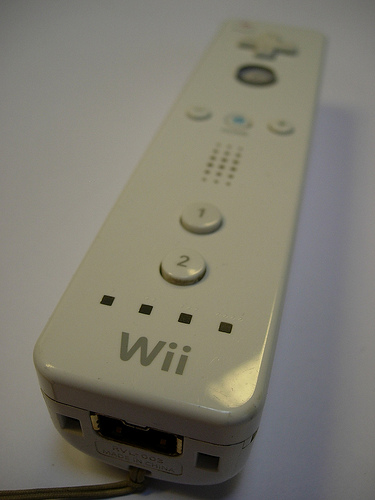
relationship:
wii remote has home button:
[16, 14, 341, 483] [237, 63, 272, 92]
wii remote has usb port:
[16, 14, 341, 483] [93, 409, 183, 458]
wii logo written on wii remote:
[111, 328, 196, 377] [16, 14, 341, 483]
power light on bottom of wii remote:
[100, 292, 116, 308] [16, 14, 341, 483]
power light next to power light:
[178, 311, 195, 326] [216, 318, 236, 336]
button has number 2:
[160, 249, 204, 280] [179, 254, 191, 270]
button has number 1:
[180, 200, 220, 229] [198, 208, 208, 221]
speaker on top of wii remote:
[200, 137, 250, 189] [16, 14, 341, 483]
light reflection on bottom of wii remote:
[206, 344, 266, 414] [16, 14, 341, 483]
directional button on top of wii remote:
[236, 28, 303, 64] [16, 14, 341, 483]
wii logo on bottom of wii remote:
[111, 328, 196, 377] [16, 14, 341, 483]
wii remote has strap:
[16, 14, 341, 483] [2, 454, 148, 499]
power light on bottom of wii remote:
[218, 321, 233, 334] [16, 14, 341, 483]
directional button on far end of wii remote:
[236, 28, 303, 64] [16, 14, 341, 483]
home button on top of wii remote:
[237, 63, 272, 92] [16, 14, 341, 483]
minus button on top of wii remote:
[188, 103, 216, 123] [16, 14, 341, 483]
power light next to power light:
[100, 292, 116, 308] [137, 302, 156, 317]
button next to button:
[160, 249, 204, 280] [180, 200, 220, 229]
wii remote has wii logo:
[16, 14, 341, 483] [111, 328, 196, 377]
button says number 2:
[160, 249, 204, 280] [179, 254, 191, 270]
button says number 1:
[180, 200, 220, 229] [198, 208, 208, 221]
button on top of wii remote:
[181, 201, 221, 234] [16, 14, 341, 483]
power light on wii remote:
[100, 292, 116, 308] [16, 14, 341, 483]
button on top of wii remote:
[160, 249, 204, 280] [16, 14, 341, 483]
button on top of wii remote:
[180, 200, 220, 229] [16, 14, 341, 483]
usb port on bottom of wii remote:
[93, 409, 183, 458] [16, 14, 341, 483]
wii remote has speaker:
[16, 14, 341, 483] [200, 137, 250, 189]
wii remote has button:
[16, 14, 341, 483] [160, 249, 204, 280]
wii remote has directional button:
[16, 14, 341, 483] [236, 28, 303, 64]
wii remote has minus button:
[16, 14, 341, 483] [188, 103, 216, 123]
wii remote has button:
[16, 14, 341, 483] [180, 200, 220, 229]